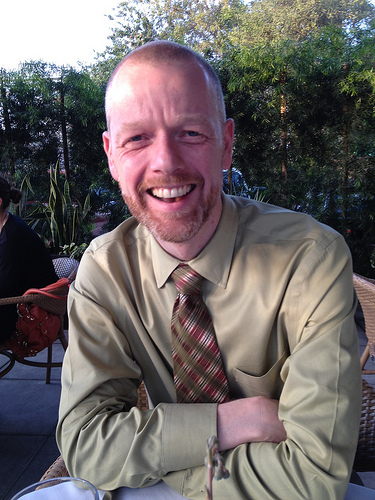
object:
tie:
[171, 263, 232, 404]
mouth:
[139, 171, 203, 213]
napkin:
[17, 480, 94, 500]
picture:
[0, 0, 375, 500]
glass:
[8, 480, 98, 499]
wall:
[115, 64, 165, 80]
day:
[0, 0, 111, 64]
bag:
[15, 278, 71, 357]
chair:
[0, 257, 80, 385]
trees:
[0, 0, 375, 245]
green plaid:
[174, 318, 195, 349]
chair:
[351, 271, 375, 376]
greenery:
[0, 0, 373, 264]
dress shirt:
[55, 189, 362, 499]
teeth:
[152, 185, 191, 199]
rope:
[204, 435, 230, 500]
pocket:
[232, 344, 289, 398]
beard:
[118, 169, 223, 244]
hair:
[104, 40, 226, 132]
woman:
[0, 176, 60, 344]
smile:
[118, 146, 222, 242]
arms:
[55, 307, 361, 500]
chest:
[121, 260, 282, 403]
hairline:
[117, 59, 205, 73]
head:
[102, 40, 234, 243]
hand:
[249, 395, 288, 444]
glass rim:
[17, 475, 99, 496]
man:
[55, 40, 363, 500]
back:
[20, 288, 73, 350]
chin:
[153, 211, 203, 242]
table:
[103, 480, 374, 498]